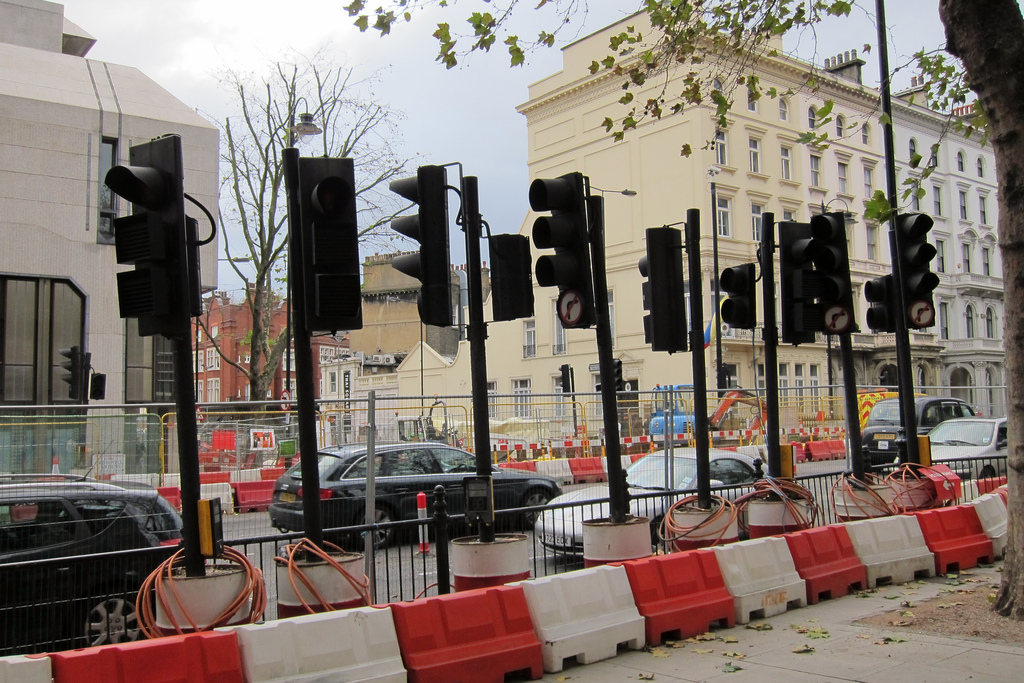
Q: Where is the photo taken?
A: In Europe.